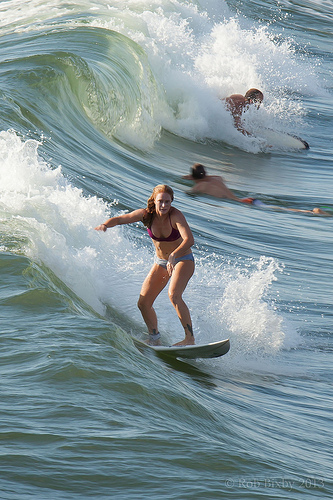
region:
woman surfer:
[110, 188, 211, 346]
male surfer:
[218, 79, 280, 153]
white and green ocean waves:
[39, 15, 77, 72]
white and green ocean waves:
[10, 419, 61, 452]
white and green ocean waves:
[172, 390, 204, 434]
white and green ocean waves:
[256, 319, 284, 361]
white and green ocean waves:
[35, 213, 74, 277]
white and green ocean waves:
[33, 179, 94, 237]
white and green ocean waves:
[66, 52, 114, 106]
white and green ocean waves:
[124, 24, 153, 57]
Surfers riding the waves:
[21, 11, 317, 444]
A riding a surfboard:
[101, 179, 224, 364]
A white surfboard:
[128, 321, 252, 367]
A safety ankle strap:
[136, 322, 166, 345]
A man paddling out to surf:
[185, 149, 330, 241]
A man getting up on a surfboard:
[218, 83, 306, 163]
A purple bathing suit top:
[139, 221, 182, 241]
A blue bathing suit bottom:
[152, 253, 207, 272]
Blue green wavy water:
[34, 314, 284, 487]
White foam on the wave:
[10, 143, 103, 339]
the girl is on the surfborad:
[117, 164, 257, 392]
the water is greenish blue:
[48, 391, 319, 477]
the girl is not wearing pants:
[117, 258, 294, 334]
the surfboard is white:
[132, 308, 320, 397]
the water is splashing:
[191, 245, 326, 366]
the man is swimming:
[134, 148, 302, 197]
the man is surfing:
[180, 65, 322, 170]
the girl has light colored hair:
[124, 173, 174, 215]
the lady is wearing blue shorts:
[131, 250, 256, 295]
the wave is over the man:
[103, 49, 331, 133]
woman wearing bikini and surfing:
[90, 182, 201, 364]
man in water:
[186, 158, 251, 218]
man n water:
[202, 63, 258, 141]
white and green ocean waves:
[31, 360, 66, 399]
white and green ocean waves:
[250, 396, 270, 409]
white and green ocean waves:
[136, 463, 187, 499]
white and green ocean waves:
[231, 390, 279, 427]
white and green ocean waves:
[97, 385, 135, 427]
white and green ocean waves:
[42, 269, 75, 307]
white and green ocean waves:
[28, 161, 63, 196]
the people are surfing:
[67, 24, 296, 376]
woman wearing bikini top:
[133, 210, 187, 250]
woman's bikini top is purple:
[136, 210, 184, 243]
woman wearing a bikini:
[143, 252, 206, 273]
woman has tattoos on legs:
[141, 319, 201, 338]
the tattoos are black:
[146, 321, 201, 342]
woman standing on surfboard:
[87, 173, 237, 367]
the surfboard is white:
[125, 321, 235, 367]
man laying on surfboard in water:
[181, 158, 332, 229]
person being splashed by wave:
[212, 78, 311, 158]